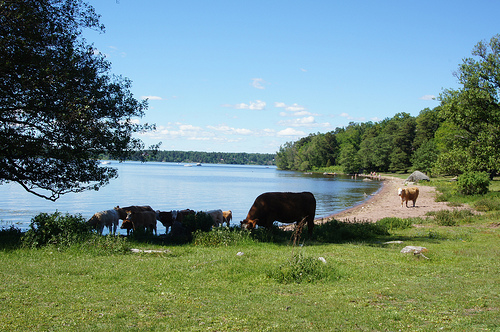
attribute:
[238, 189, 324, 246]
cow — one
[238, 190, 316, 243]
cow — one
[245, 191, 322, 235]
cow — one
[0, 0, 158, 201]
tree — dark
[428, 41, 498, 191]
tree — dark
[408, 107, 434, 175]
tree — dark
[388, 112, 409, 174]
tree — dark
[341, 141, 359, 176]
tree — dark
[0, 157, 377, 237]
water — some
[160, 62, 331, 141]
clouds — small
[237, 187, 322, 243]
cow — dark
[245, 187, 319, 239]
cow — one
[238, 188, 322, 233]
cow — one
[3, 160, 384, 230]
water — calm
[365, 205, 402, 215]
sand — tan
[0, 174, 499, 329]
grass — short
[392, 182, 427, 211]
cow — one